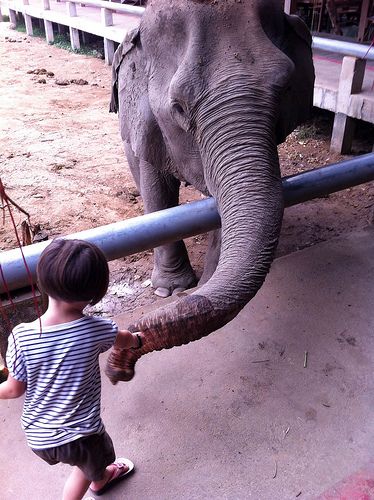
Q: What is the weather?
A: Cloudy.